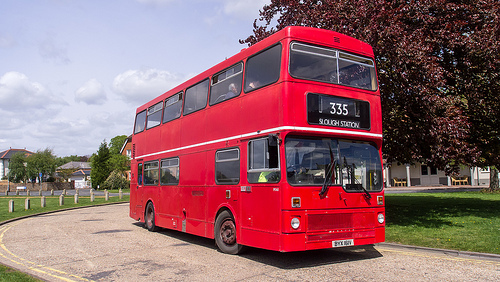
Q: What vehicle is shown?
A: A bus.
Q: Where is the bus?
A: On the road.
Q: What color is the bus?
A: Red.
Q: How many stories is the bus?
A: Two.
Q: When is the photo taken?
A: Daytime.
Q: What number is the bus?
A: 335.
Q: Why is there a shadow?
A: It is sunny.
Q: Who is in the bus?
A: A driver.